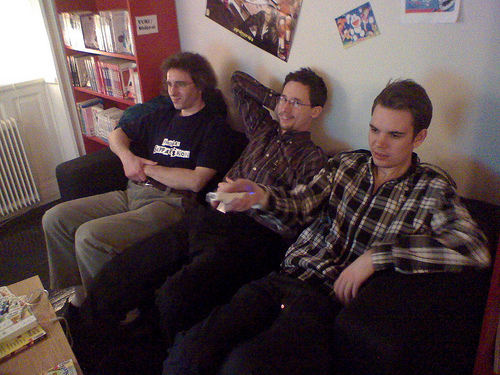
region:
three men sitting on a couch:
[37, 45, 490, 372]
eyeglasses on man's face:
[275, 90, 312, 112]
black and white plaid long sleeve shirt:
[245, 143, 492, 300]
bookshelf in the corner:
[57, 25, 180, 166]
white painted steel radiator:
[1, 118, 43, 217]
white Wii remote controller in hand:
[204, 180, 263, 218]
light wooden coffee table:
[2, 265, 74, 374]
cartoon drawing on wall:
[331, 1, 388, 50]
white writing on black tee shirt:
[147, 136, 193, 163]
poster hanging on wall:
[202, 1, 306, 63]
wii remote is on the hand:
[205, 173, 272, 228]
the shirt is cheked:
[307, 167, 467, 268]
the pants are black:
[113, 235, 223, 337]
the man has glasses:
[245, 75, 327, 167]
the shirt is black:
[121, 117, 206, 185]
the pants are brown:
[35, 187, 130, 251]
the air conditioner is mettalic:
[3, 123, 35, 213]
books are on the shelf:
[73, 75, 133, 134]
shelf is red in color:
[66, 68, 157, 150]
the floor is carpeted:
[13, 235, 58, 270]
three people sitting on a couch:
[39, 48, 499, 374]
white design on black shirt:
[141, 125, 196, 160]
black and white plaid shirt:
[257, 145, 488, 306]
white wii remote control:
[197, 181, 259, 203]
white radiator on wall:
[0, 107, 45, 227]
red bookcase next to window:
[55, 26, 181, 156]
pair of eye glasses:
[271, 87, 321, 108]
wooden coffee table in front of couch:
[0, 266, 85, 362]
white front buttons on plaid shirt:
[245, 131, 280, 181]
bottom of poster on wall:
[197, 0, 307, 65]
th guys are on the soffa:
[26, 67, 497, 339]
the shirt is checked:
[316, 163, 472, 286]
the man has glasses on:
[258, 73, 328, 170]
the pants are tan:
[51, 197, 144, 254]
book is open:
[0, 288, 40, 365]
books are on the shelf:
[67, 41, 132, 117]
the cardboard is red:
[64, 35, 174, 99]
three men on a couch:
[34, 49, 494, 374]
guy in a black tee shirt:
[40, 47, 238, 294]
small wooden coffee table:
[1, 270, 84, 373]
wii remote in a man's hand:
[203, 186, 267, 211]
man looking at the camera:
[85, 60, 330, 353]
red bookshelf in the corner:
[44, 2, 194, 160]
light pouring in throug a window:
[1, 3, 63, 93]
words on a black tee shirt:
[149, 135, 203, 165]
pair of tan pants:
[36, 172, 192, 294]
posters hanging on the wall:
[199, 2, 467, 64]